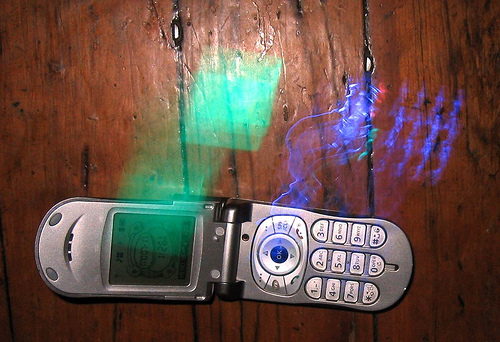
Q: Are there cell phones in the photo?
A: Yes, there is a cell phone.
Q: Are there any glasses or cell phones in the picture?
A: Yes, there is a cell phone.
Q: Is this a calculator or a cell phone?
A: This is a cell phone.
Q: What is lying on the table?
A: The cellphone is lying on the table.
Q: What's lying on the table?
A: The cellphone is lying on the table.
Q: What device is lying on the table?
A: The device is a cell phone.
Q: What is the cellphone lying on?
A: The cellphone is lying on the table.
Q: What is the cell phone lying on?
A: The cellphone is lying on the table.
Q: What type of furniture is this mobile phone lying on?
A: The mobile phone is lying on the table.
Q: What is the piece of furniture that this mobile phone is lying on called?
A: The piece of furniture is a table.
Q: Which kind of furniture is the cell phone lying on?
A: The mobile phone is lying on the table.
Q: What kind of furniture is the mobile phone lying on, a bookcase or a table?
A: The mobile phone is lying on a table.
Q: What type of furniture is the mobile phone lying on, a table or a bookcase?
A: The mobile phone is lying on a table.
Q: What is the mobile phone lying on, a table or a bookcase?
A: The mobile phone is lying on a table.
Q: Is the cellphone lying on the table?
A: Yes, the cellphone is lying on the table.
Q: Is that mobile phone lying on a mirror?
A: No, the mobile phone is lying on the table.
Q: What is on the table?
A: The cell phone is on the table.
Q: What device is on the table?
A: The device is a cell phone.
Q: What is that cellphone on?
A: The cellphone is on the table.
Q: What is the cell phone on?
A: The cellphone is on the table.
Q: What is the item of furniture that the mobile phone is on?
A: The piece of furniture is a table.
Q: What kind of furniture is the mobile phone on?
A: The mobile phone is on the table.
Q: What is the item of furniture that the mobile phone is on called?
A: The piece of furniture is a table.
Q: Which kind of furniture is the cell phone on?
A: The mobile phone is on the table.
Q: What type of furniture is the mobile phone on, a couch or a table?
A: The mobile phone is on a table.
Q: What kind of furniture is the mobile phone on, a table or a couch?
A: The mobile phone is on a table.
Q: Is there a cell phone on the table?
A: Yes, there is a cell phone on the table.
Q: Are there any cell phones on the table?
A: Yes, there is a cell phone on the table.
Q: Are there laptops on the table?
A: No, there is a cell phone on the table.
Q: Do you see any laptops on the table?
A: No, there is a cell phone on the table.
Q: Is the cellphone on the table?
A: Yes, the cellphone is on the table.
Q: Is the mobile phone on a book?
A: No, the mobile phone is on the table.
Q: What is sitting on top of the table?
A: The cellphone is sitting on top of the table.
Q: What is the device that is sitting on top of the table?
A: The device is a cell phone.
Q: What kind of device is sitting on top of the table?
A: The device is a cell phone.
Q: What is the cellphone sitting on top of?
A: The cellphone is sitting on top of the table.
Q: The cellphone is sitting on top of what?
A: The cellphone is sitting on top of the table.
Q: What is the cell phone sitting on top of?
A: The cellphone is sitting on top of the table.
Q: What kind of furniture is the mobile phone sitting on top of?
A: The mobile phone is sitting on top of the table.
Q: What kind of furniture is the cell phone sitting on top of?
A: The mobile phone is sitting on top of the table.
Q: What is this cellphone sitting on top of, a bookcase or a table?
A: The cellphone is sitting on top of a table.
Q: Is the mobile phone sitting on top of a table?
A: Yes, the mobile phone is sitting on top of a table.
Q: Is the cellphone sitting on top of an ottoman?
A: No, the cellphone is sitting on top of a table.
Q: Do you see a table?
A: Yes, there is a table.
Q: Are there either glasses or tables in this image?
A: Yes, there is a table.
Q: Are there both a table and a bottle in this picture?
A: No, there is a table but no bottles.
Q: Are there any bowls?
A: No, there are no bowls.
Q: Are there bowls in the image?
A: No, there are no bowls.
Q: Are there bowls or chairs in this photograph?
A: No, there are no bowls or chairs.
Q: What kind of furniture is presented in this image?
A: The furniture is a table.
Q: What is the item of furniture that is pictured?
A: The piece of furniture is a table.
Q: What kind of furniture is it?
A: The piece of furniture is a table.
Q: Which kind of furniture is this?
A: This is a table.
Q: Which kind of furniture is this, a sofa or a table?
A: This is a table.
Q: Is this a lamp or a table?
A: This is a table.